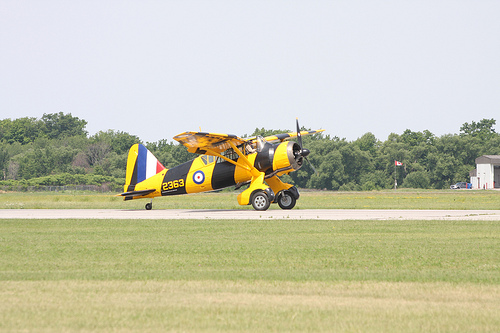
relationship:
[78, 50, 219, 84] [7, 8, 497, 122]
clouds in sky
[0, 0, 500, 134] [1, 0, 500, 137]
clouds in sky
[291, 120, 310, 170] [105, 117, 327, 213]
propeller on plane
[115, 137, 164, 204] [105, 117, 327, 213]
tail of plane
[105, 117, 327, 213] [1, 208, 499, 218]
plane on runway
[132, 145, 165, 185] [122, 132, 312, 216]
stripes on plane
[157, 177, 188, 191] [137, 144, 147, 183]
numbers on stripes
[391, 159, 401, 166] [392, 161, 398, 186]
canadian flag on post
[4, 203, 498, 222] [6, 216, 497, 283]
runway between grass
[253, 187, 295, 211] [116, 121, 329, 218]
wheel of plane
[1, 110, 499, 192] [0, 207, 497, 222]
trees on side of runway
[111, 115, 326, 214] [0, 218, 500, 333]
airplane on ground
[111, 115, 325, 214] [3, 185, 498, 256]
airplane on ground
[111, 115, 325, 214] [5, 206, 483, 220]
airplane on runway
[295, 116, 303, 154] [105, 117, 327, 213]
propeller on plane